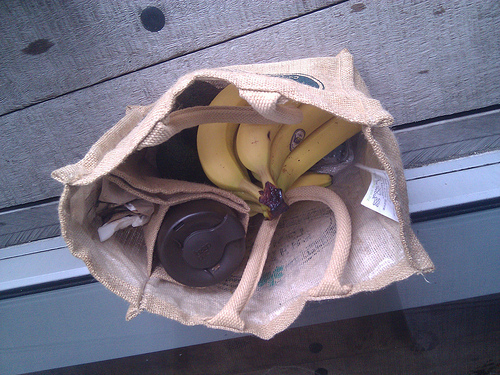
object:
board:
[0, 1, 500, 375]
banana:
[276, 115, 363, 195]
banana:
[251, 103, 335, 186]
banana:
[195, 83, 265, 202]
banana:
[291, 171, 333, 191]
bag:
[43, 49, 436, 342]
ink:
[270, 72, 325, 90]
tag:
[354, 163, 401, 224]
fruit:
[195, 84, 361, 220]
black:
[158, 210, 249, 288]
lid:
[155, 202, 247, 288]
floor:
[16, 292, 500, 375]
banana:
[234, 97, 300, 189]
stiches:
[137, 276, 151, 309]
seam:
[137, 276, 152, 311]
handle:
[206, 185, 353, 332]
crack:
[1, 0, 353, 120]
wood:
[0, 0, 346, 116]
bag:
[91, 178, 156, 243]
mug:
[148, 199, 251, 288]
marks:
[139, 6, 166, 33]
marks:
[19, 38, 57, 56]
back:
[68, 135, 407, 328]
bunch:
[192, 82, 363, 222]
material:
[96, 215, 144, 243]